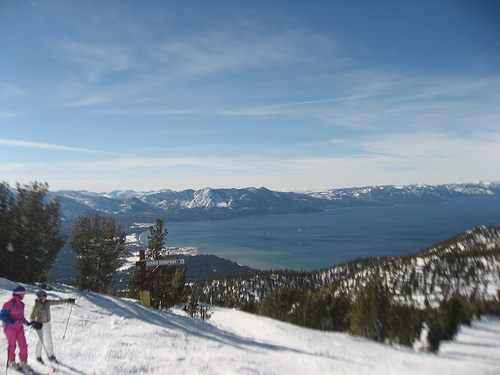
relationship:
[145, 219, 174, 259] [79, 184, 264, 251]
tree in distance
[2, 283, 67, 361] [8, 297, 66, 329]
women with jackets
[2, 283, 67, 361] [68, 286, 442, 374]
women on slope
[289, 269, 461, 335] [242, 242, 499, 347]
forest on hill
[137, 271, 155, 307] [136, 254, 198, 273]
pole holding sign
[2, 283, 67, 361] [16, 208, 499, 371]
skiers on mountain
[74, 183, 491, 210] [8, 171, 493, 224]
mountains on horizon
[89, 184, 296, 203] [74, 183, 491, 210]
snow on mountains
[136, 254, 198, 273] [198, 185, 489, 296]
sign pointing out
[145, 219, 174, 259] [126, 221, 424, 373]
tree on mountainside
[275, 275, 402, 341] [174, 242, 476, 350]
trees on slopes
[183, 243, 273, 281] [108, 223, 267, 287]
beach on bottom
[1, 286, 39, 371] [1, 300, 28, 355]
skier wearing pink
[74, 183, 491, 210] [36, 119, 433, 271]
mountains in background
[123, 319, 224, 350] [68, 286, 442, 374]
snow on ground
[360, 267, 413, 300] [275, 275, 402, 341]
snow on trees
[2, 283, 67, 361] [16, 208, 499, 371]
people on mountain